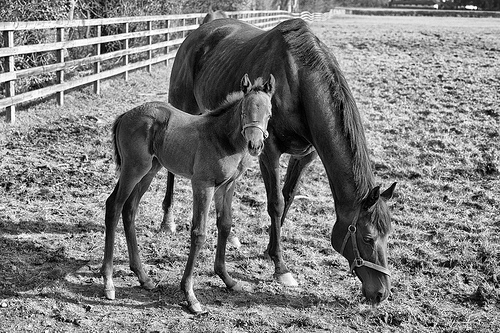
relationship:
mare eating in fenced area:
[159, 10, 400, 303] [1, 4, 496, 331]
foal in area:
[56, 108, 252, 315] [42, 15, 497, 328]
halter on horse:
[238, 83, 268, 137] [98, 70, 277, 312]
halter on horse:
[337, 192, 391, 277] [162, 15, 412, 305]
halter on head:
[236, 100, 268, 140] [234, 70, 283, 162]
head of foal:
[234, 70, 283, 162] [88, 66, 280, 313]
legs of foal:
[94, 154, 259, 315] [98, 72, 273, 322]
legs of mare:
[255, 146, 312, 296] [159, 10, 400, 303]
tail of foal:
[102, 130, 132, 172] [88, 66, 280, 313]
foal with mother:
[88, 66, 280, 313] [158, 2, 398, 303]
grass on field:
[409, 213, 486, 304] [3, 18, 492, 330]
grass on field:
[8, 34, 498, 316] [3, 18, 492, 330]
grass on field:
[452, 52, 494, 132] [381, 27, 497, 310]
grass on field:
[39, 139, 104, 203] [3, 18, 492, 330]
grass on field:
[355, 27, 426, 121] [3, 18, 492, 330]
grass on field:
[389, 57, 490, 187] [3, 18, 492, 330]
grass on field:
[366, 14, 462, 141] [3, 18, 492, 330]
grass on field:
[407, 90, 499, 218] [3, 18, 492, 330]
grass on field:
[246, 260, 383, 325] [3, 18, 492, 330]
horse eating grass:
[162, 15, 412, 305] [0, 15, 498, 332]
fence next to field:
[18, 3, 199, 92] [3, 18, 492, 330]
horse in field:
[162, 15, 412, 305] [3, 18, 492, 330]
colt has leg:
[101, 70, 282, 315] [214, 176, 241, 290]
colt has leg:
[101, 70, 282, 315] [121, 155, 163, 295]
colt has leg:
[101, 70, 282, 315] [95, 154, 152, 303]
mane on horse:
[278, 17, 395, 233] [162, 15, 412, 305]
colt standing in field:
[101, 70, 282, 315] [3, 18, 492, 330]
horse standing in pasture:
[162, 15, 412, 305] [6, 16, 497, 330]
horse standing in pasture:
[98, 70, 277, 312] [6, 16, 497, 330]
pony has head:
[104, 61, 319, 313] [213, 83, 278, 143]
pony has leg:
[93, 70, 277, 319] [212, 178, 240, 293]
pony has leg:
[93, 70, 277, 319] [177, 173, 216, 313]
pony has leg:
[93, 70, 277, 319] [121, 155, 163, 295]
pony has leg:
[93, 70, 277, 319] [97, 146, 154, 299]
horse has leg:
[157, 9, 397, 308] [268, 146, 316, 255]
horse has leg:
[157, 9, 397, 308] [262, 146, 291, 281]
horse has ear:
[171, 6, 392, 303] [382, 181, 401, 204]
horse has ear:
[171, 6, 392, 303] [363, 186, 382, 207]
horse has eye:
[157, 9, 397, 308] [362, 230, 377, 249]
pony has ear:
[110, 70, 307, 282] [263, 69, 276, 96]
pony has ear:
[110, 70, 307, 282] [236, 69, 256, 95]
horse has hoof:
[162, 15, 412, 305] [270, 269, 297, 289]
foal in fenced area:
[66, 67, 313, 252] [39, 7, 151, 103]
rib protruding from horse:
[210, 52, 238, 106] [98, 70, 277, 312]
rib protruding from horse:
[196, 41, 236, 92] [98, 70, 277, 312]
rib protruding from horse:
[211, 55, 236, 93] [98, 70, 277, 312]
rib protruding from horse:
[160, 122, 170, 165] [162, 15, 412, 305]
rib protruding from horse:
[163, 122, 177, 167] [162, 15, 412, 305]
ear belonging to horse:
[263, 72, 280, 94] [98, 70, 277, 312]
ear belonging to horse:
[238, 73, 254, 96] [98, 70, 277, 312]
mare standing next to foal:
[159, 10, 400, 303] [98, 72, 273, 322]